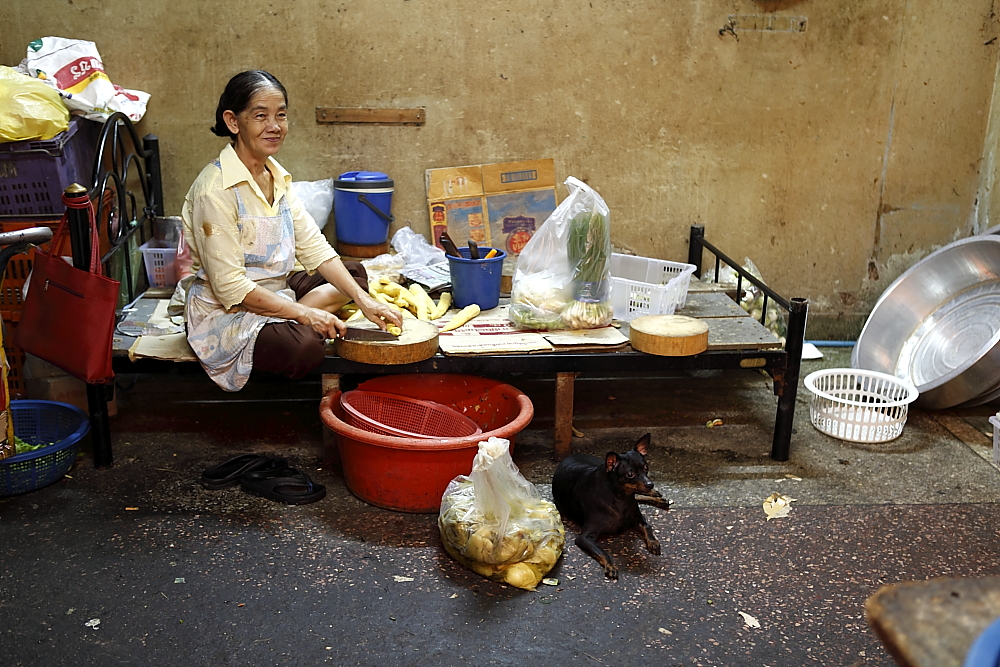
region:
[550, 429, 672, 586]
Black dog laying on ground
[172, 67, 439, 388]
Old woman cutting food on cutting board while smiling.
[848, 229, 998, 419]
Metal pan leaning to the right.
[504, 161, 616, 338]
Transparent plastic bag with produce inside.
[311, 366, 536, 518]
Red bins stacked inside one another.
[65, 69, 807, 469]
Woman sitting on a bed frame preparing food.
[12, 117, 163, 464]
Red purse wrapped around the post of a bed frame.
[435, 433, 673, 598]
Transparent bag with food beside a dog.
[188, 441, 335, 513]
Black sandals on the ground.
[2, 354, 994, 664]
Dirty floor with various objects on it.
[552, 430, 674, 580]
A small black and brown dog laying on the ground.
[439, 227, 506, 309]
A blue bucket holding various utensils.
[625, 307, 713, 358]
A small, round chopping block made of wood.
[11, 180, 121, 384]
A red hand bag hanging from the bed post.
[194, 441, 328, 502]
A pair of small black flip flops.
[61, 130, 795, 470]
A bed frame being used as a work table.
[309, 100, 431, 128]
A strip of wood nailed to the wall.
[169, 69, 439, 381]
An old lady chopping peppers on a wooden block.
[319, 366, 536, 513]
Large red basket holding a smaller red basket.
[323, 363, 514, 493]
red bucket under the table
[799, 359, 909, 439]
white basket on the ground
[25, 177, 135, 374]
red bag on the bed post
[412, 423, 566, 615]
plastic bag on the ground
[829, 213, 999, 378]
silver pan against the wall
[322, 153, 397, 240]
blue cooler against the wall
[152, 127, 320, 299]
woman wearing a yellow shirt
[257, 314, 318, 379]
woman wearing brown pants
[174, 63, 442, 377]
woman cutting up vegetables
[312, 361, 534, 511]
a large red plastic tub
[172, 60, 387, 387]
woman wearing an apron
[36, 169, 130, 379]
A red purse hanging from the bed post.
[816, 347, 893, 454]
A white basket on the ground.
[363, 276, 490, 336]
Yellow bananas on the table.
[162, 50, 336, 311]
A lady sitting on the bed.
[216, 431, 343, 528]
The cord is black.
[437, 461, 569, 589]
A plastic bag is next to the dog.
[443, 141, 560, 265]
A book leaning against the wall.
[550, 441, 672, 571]
The dog is small and black.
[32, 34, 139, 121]
Paper on top of the purple basket.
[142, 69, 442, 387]
Woman with dark hair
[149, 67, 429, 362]
Woman with black hair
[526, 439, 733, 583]
Dog on the ground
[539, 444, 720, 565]
Black dog on ground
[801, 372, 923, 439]
Basket on the ground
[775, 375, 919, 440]
White basket on ground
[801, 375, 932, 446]
Laundry basket on ground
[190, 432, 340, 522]
Shoes on the ground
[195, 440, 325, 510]
Black shoes on ground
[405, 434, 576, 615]
Bag on the ground